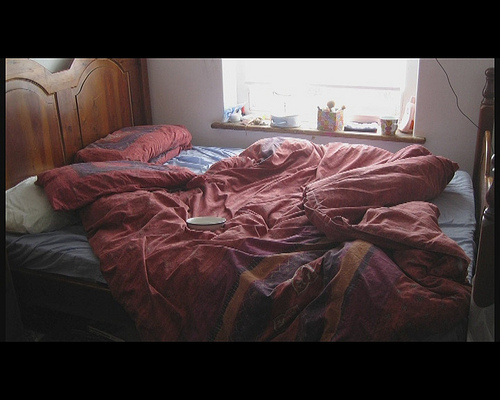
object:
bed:
[0, 59, 492, 338]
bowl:
[179, 213, 230, 234]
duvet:
[66, 129, 474, 341]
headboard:
[0, 57, 157, 189]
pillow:
[5, 163, 85, 241]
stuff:
[302, 97, 350, 138]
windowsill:
[203, 97, 427, 144]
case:
[69, 118, 198, 170]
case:
[24, 142, 202, 213]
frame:
[463, 61, 500, 316]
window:
[196, 58, 438, 144]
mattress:
[0, 130, 477, 337]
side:
[137, 55, 496, 159]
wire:
[432, 60, 485, 138]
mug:
[377, 113, 403, 140]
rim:
[186, 221, 227, 228]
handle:
[391, 121, 399, 131]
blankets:
[5, 134, 478, 344]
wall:
[2, 57, 498, 179]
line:
[6, 260, 111, 285]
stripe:
[123, 65, 137, 128]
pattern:
[4, 59, 143, 176]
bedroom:
[2, 54, 500, 339]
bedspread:
[33, 121, 473, 341]